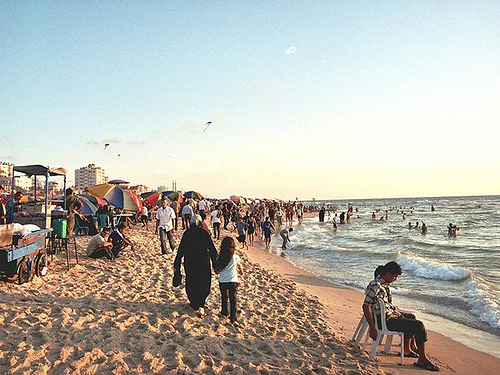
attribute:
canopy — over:
[14, 159, 69, 181]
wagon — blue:
[5, 221, 51, 277]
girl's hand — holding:
[213, 261, 219, 278]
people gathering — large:
[0, 185, 460, 372]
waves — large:
[401, 252, 498, 319]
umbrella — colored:
[84, 180, 146, 215]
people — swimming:
[304, 183, 464, 249]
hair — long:
[215, 234, 237, 275]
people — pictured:
[29, 164, 470, 336]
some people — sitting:
[193, 154, 305, 264]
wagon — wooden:
[2, 215, 55, 295]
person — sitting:
[362, 263, 437, 373]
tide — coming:
[264, 197, 498, 335]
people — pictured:
[169, 200, 254, 320]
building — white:
[74, 160, 103, 190]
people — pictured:
[21, 178, 467, 373]